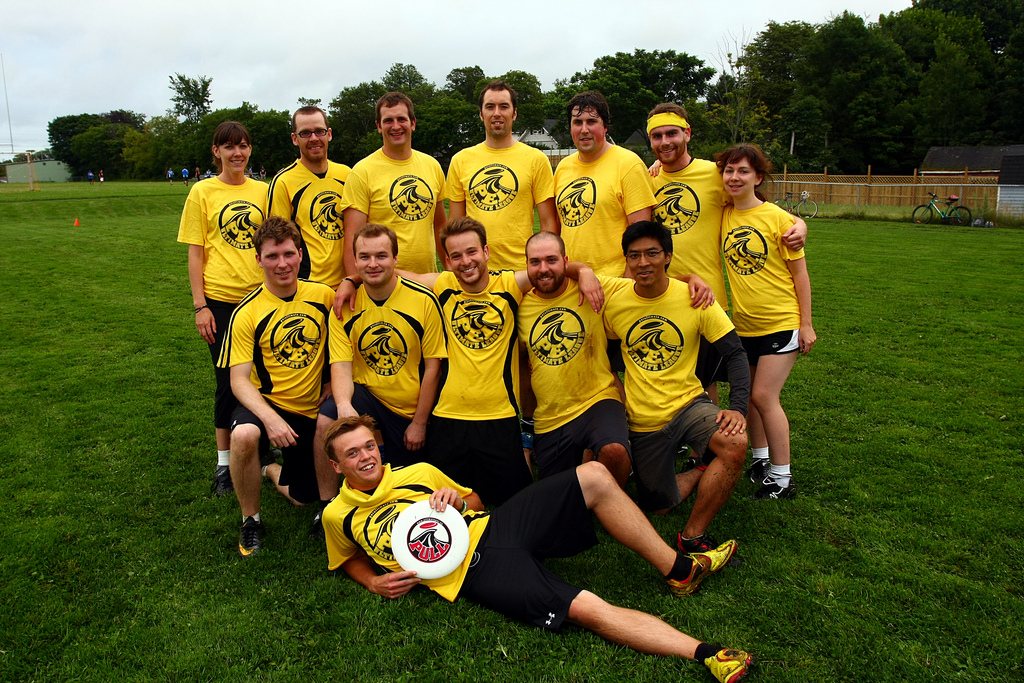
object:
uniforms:
[720, 203, 805, 359]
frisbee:
[389, 500, 469, 580]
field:
[0, 180, 1022, 683]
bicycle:
[912, 191, 973, 226]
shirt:
[320, 462, 492, 603]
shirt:
[176, 175, 272, 305]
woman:
[176, 121, 275, 502]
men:
[640, 101, 725, 345]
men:
[213, 218, 344, 560]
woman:
[712, 146, 816, 502]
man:
[265, 107, 353, 296]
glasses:
[293, 128, 328, 139]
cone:
[74, 218, 79, 227]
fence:
[753, 171, 1000, 222]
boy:
[318, 414, 754, 683]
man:
[517, 230, 632, 491]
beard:
[528, 270, 567, 294]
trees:
[46, 0, 1024, 184]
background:
[0, 0, 1024, 180]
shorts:
[458, 465, 600, 634]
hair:
[622, 220, 674, 273]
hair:
[714, 144, 777, 203]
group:
[175, 79, 816, 683]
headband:
[644, 111, 690, 135]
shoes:
[701, 643, 758, 683]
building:
[5, 161, 73, 185]